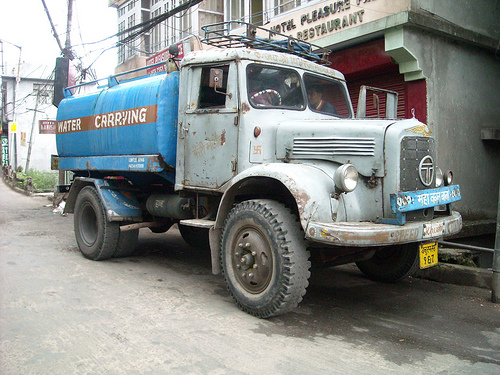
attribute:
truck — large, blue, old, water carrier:
[45, 33, 466, 320]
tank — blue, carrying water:
[48, 53, 179, 172]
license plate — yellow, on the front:
[419, 243, 441, 270]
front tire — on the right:
[217, 200, 313, 315]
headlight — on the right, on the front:
[331, 161, 358, 195]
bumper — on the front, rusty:
[309, 211, 468, 246]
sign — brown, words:
[54, 103, 163, 138]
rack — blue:
[201, 21, 335, 67]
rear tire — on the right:
[75, 187, 141, 263]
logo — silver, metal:
[416, 155, 438, 188]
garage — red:
[323, 50, 423, 120]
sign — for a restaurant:
[265, 0, 375, 46]